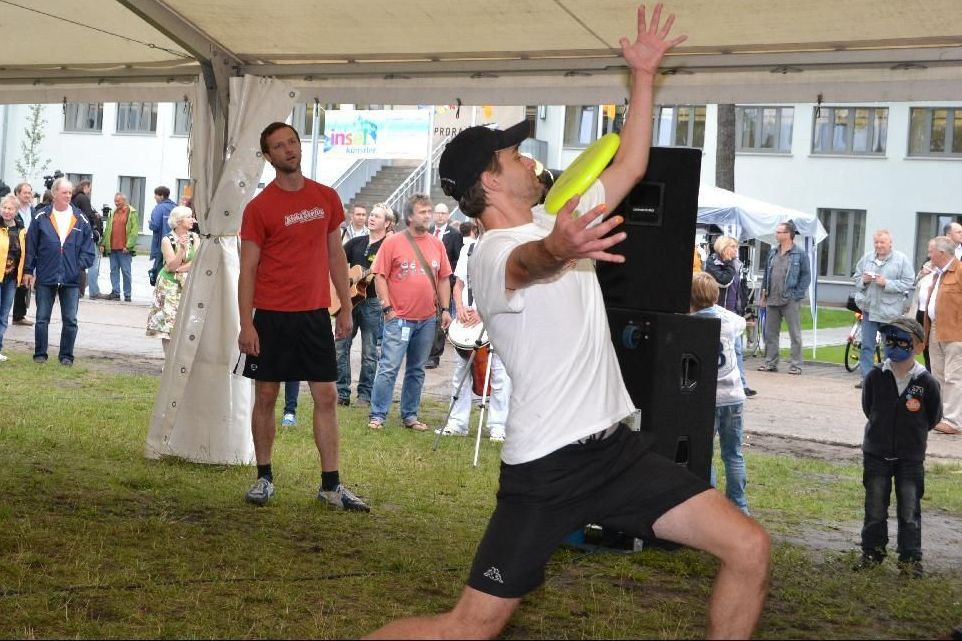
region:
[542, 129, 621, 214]
yellow frisbee in air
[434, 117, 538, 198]
black baseball cap on man with frisbee's head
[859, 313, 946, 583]
boy with his face painted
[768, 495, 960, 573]
mud patch on ground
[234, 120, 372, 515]
man in red shirt watching man in frisbee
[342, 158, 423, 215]
gray stairs in background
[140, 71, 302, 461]
sides of tent wrapped around pole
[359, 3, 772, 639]
man performing with a yellow frisbee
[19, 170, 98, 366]
man in blue jacket and white shirt looking away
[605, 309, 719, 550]
large black speaker on ground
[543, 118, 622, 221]
the frisbee is yellow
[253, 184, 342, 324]
the shirt is red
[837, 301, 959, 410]
a little boy is wearing a blue mask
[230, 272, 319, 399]
the nam is wearing black shorts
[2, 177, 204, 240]
a group of people gathered together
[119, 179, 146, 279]
man with a green jacket on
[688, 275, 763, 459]
kid standing behind speakers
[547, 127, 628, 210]
frisbee is light yellow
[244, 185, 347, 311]
red shirt on a man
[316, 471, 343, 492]
black sock on man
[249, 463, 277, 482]
black sock on man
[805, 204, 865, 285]
window on the building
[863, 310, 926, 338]
hat on boy's head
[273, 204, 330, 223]
words on top of shirt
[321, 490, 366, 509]
shoe on a foot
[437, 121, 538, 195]
hat on man's head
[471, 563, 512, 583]
white design on black shorts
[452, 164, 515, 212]
the ear of a young man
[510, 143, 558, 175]
the nose of a young man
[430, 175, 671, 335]
the arm of a young man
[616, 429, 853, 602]
the knee of a young man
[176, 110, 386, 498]
a man wearing a red shirt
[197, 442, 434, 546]
a man wearing white shoes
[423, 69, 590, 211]
a man wearing a hat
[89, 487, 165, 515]
dirt in the grass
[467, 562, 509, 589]
logo on the shorts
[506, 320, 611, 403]
man is wearing a white shirt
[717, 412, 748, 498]
a person wearing light blue jeans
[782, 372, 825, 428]
the sidewalk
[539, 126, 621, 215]
A yellow frisbee.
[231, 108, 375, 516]
A man wearing red and black clothing.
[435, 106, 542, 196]
A black baseball style cap.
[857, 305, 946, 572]
A young boy with a blue face.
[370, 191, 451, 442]
A man in a red shirt and jeans.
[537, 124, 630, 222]
the frisbee is green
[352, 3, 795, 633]
man is bend backward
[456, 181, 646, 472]
tee shirt is white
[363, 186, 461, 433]
man has red tee shirt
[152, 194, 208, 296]
woman has gray hair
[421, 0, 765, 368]
man trying to catch a fresbee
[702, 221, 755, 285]
woman has blonde hair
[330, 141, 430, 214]
the steps on front a building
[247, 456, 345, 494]
the socks are black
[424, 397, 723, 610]
black shorts with white logo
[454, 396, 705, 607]
black shorts with white logo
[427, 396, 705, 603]
black shorts with white logo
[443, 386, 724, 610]
black shorts with white logo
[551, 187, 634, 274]
Hand of a man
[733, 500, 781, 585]
Knee of a man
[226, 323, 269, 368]
Hand of a man